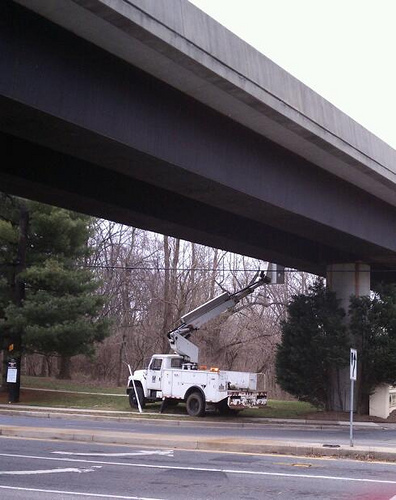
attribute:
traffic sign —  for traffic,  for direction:
[347, 349, 360, 380]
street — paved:
[42, 393, 305, 499]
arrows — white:
[112, 440, 177, 480]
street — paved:
[0, 401, 394, 498]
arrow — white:
[0, 463, 103, 476]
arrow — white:
[51, 447, 175, 461]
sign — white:
[347, 346, 360, 382]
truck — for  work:
[126, 271, 270, 414]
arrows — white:
[3, 440, 181, 479]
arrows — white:
[0, 407, 394, 498]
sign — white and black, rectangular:
[348, 346, 358, 378]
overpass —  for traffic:
[2, 2, 395, 267]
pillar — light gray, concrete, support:
[309, 251, 381, 413]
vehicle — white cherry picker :
[121, 342, 246, 420]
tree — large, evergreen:
[17, 210, 112, 387]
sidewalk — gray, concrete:
[306, 414, 334, 425]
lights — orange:
[186, 346, 240, 388]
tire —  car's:
[186, 389, 205, 415]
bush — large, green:
[264, 287, 395, 416]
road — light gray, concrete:
[0, 400, 395, 497]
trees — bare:
[100, 244, 151, 369]